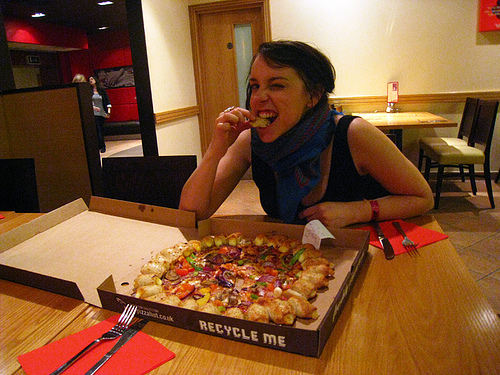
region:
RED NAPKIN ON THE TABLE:
[12, 315, 182, 373]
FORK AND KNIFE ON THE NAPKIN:
[52, 290, 146, 373]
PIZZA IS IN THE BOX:
[131, 190, 345, 350]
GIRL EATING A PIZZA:
[194, 43, 356, 161]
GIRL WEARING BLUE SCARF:
[235, 107, 356, 225]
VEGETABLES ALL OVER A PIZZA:
[173, 242, 305, 331]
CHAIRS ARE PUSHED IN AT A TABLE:
[405, 83, 497, 220]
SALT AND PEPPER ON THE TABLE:
[377, 97, 407, 122]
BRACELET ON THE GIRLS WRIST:
[357, 194, 387, 230]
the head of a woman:
[224, 53, 334, 156]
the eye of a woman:
[246, 60, 311, 100]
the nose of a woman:
[243, 80, 280, 116]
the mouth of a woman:
[243, 93, 293, 135]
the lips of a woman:
[241, 95, 306, 137]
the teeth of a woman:
[243, 103, 294, 140]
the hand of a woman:
[301, 199, 341, 237]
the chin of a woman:
[241, 123, 287, 155]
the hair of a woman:
[218, 6, 355, 137]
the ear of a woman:
[290, 71, 330, 122]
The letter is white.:
[196, 317, 208, 334]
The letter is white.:
[206, 315, 217, 335]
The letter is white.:
[213, 320, 225, 337]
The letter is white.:
[223, 321, 233, 338]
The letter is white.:
[230, 325, 243, 341]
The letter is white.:
[239, 325, 251, 341]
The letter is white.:
[246, 328, 260, 347]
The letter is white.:
[261, 329, 278, 351]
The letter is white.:
[275, 330, 287, 349]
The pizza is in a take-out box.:
[1, 188, 376, 367]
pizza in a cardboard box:
[131, 228, 321, 327]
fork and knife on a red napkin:
[372, 215, 418, 262]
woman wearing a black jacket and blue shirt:
[86, 75, 116, 152]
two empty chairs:
[428, 88, 498, 205]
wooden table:
[373, 263, 455, 371]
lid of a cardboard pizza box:
[1, 203, 183, 298]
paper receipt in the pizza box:
[299, 220, 336, 248]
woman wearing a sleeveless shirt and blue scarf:
[184, 39, 435, 224]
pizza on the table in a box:
[146, 242, 317, 320]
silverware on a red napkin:
[18, 308, 162, 374]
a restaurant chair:
[424, 96, 499, 218]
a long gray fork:
[42, 300, 142, 373]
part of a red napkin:
[16, 310, 174, 373]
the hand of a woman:
[210, 107, 257, 156]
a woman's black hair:
[242, 40, 343, 137]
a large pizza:
[127, 225, 336, 334]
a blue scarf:
[245, 106, 346, 221]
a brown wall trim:
[152, 99, 206, 127]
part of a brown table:
[346, 105, 456, 135]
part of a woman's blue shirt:
[91, 90, 107, 115]